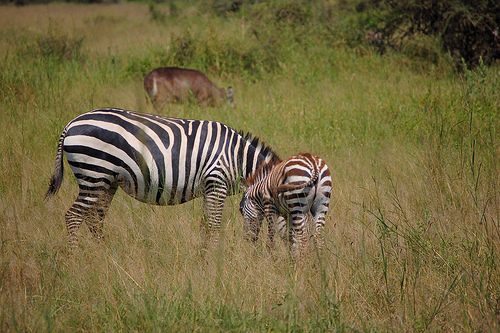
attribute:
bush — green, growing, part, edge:
[70, 62, 107, 77]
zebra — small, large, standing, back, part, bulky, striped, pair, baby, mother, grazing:
[269, 168, 315, 242]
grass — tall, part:
[6, 59, 50, 101]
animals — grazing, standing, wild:
[121, 51, 352, 214]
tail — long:
[45, 134, 72, 190]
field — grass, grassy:
[256, 37, 308, 68]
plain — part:
[74, 10, 138, 47]